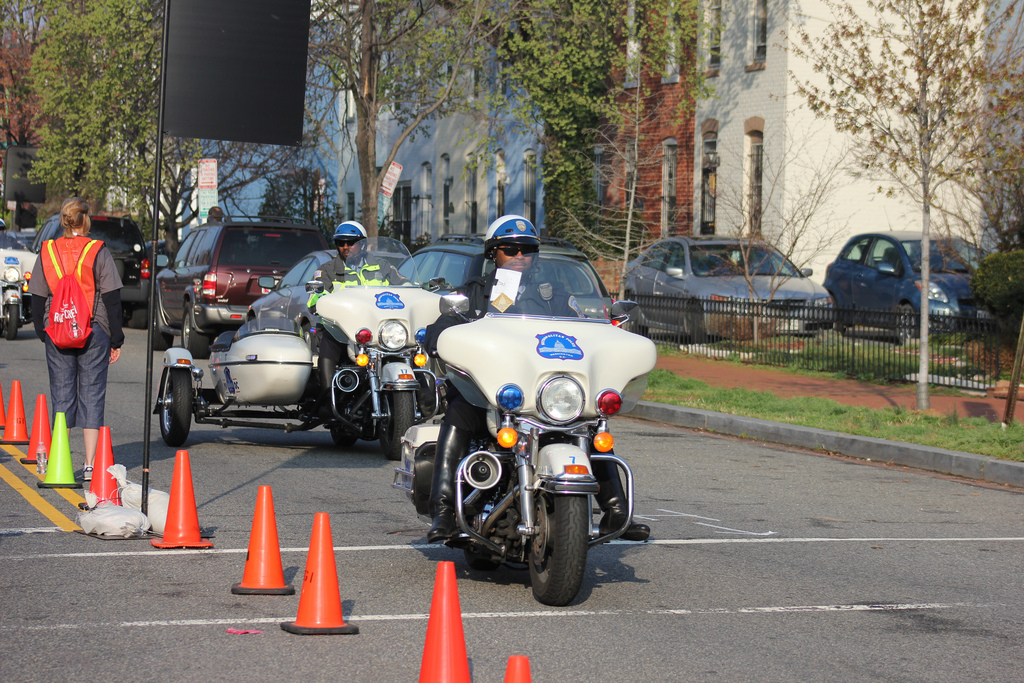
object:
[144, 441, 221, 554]
cones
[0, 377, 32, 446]
cone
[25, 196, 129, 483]
woman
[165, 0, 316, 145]
sign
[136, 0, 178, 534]
pole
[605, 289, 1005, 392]
fence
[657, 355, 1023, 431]
sidewalk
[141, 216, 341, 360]
suv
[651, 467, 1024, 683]
street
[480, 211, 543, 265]
helmet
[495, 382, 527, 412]
light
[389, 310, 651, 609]
bike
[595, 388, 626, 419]
light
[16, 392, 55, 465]
cone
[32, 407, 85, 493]
cone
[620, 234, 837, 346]
car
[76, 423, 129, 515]
cone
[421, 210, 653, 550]
cop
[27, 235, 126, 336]
vest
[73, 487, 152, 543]
sandbags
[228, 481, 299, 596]
cones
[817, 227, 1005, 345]
car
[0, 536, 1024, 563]
lines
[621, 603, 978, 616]
lines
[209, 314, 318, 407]
sidecar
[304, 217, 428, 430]
cop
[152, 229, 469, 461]
motorcycle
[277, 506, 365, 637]
cones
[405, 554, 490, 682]
cones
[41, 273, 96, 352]
backpack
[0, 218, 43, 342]
cars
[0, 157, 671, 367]
streetside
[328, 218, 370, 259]
helmets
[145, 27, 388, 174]
sign